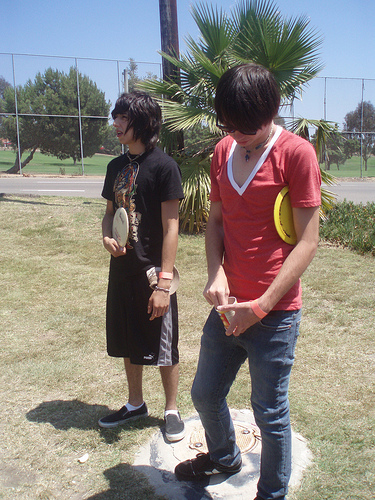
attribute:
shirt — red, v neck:
[201, 133, 325, 318]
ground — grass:
[3, 193, 374, 498]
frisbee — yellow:
[274, 185, 299, 249]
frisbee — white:
[111, 205, 130, 260]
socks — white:
[123, 402, 180, 418]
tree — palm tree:
[137, 8, 326, 261]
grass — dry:
[1, 193, 371, 497]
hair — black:
[215, 62, 282, 132]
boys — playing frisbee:
[94, 59, 329, 499]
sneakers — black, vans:
[101, 407, 187, 443]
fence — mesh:
[3, 49, 374, 189]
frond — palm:
[242, 8, 288, 74]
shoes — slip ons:
[96, 401, 188, 444]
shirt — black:
[95, 148, 188, 274]